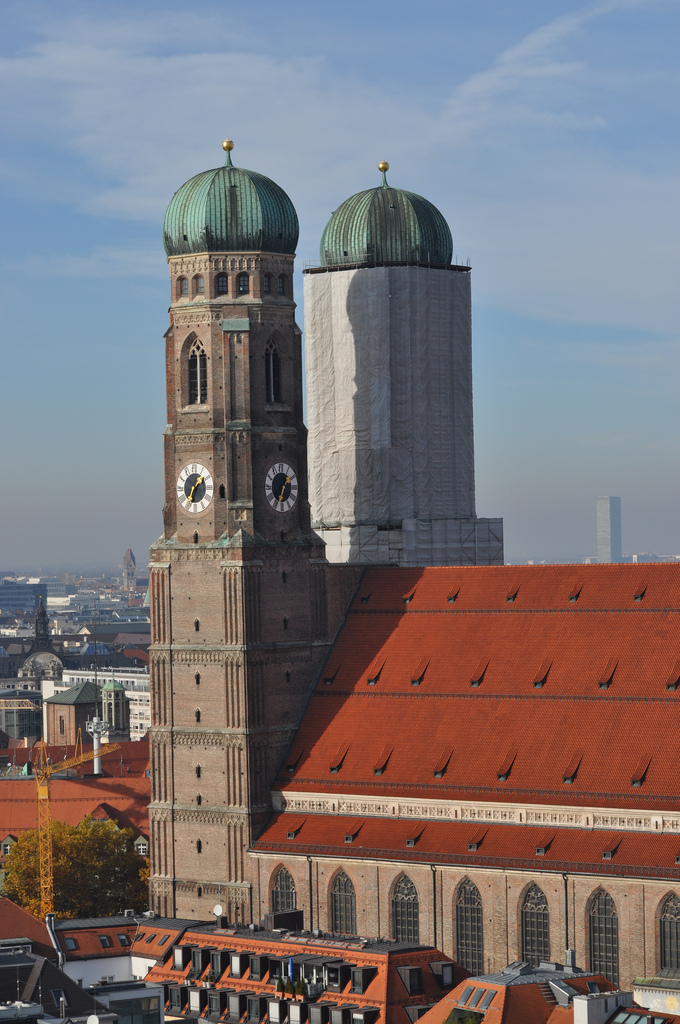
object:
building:
[244, 555, 680, 991]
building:
[303, 161, 505, 564]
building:
[597, 495, 622, 563]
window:
[388, 870, 419, 946]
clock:
[176, 463, 215, 513]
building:
[149, 139, 335, 930]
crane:
[32, 737, 121, 920]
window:
[655, 889, 680, 977]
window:
[585, 882, 618, 991]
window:
[452, 874, 484, 976]